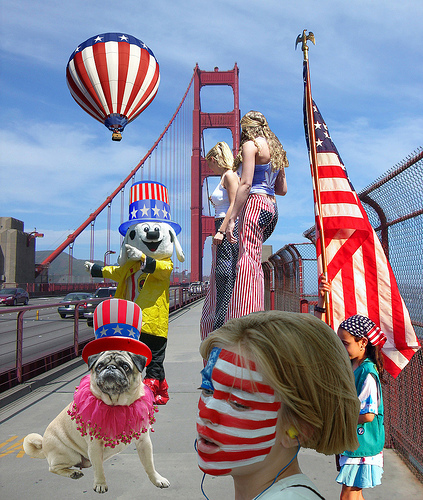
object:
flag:
[302, 58, 423, 380]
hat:
[117, 180, 181, 237]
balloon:
[63, 30, 162, 143]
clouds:
[0, 0, 422, 282]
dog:
[23, 350, 169, 495]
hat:
[80, 297, 151, 365]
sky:
[0, 0, 422, 296]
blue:
[34, 74, 58, 94]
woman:
[224, 110, 288, 325]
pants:
[225, 195, 279, 320]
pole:
[37, 67, 199, 273]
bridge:
[0, 61, 421, 499]